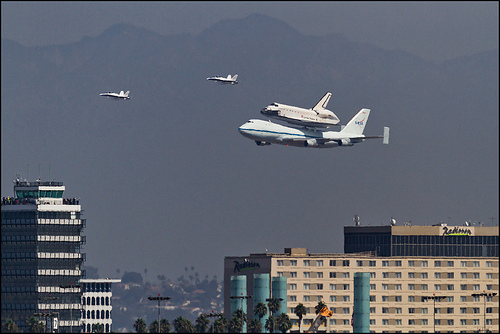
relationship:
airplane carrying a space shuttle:
[240, 91, 393, 153] [260, 94, 342, 129]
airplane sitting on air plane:
[260, 91, 341, 128] [235, 100, 394, 152]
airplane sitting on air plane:
[260, 91, 341, 128] [95, 85, 130, 100]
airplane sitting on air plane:
[260, 91, 341, 128] [207, 71, 239, 88]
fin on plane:
[345, 103, 371, 136] [228, 106, 400, 159]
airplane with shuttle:
[238, 108, 391, 149] [263, 90, 339, 129]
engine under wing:
[302, 137, 324, 148] [302, 128, 393, 145]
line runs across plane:
[243, 124, 314, 140] [216, 101, 388, 160]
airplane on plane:
[260, 91, 341, 128] [56, 82, 179, 151]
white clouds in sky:
[20, 18, 112, 69] [3, 5, 499, 292]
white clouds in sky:
[28, 45, 88, 100] [5, 2, 497, 331]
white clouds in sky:
[29, 35, 150, 79] [43, 23, 413, 68]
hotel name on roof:
[440, 224, 480, 234] [343, 221, 498, 229]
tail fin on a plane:
[231, 73, 239, 83] [205, 71, 238, 83]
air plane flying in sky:
[99, 90, 131, 101] [30, 23, 462, 160]